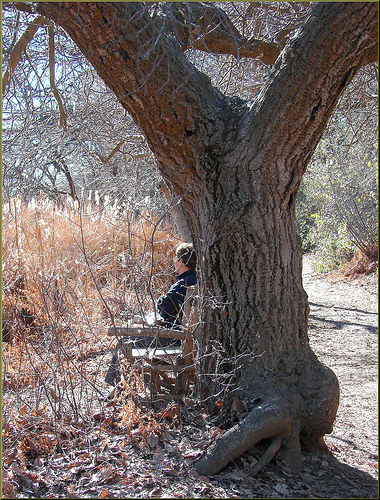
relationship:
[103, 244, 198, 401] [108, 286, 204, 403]
man on bench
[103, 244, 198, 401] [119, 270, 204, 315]
man wearing jacket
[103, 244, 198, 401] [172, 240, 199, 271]
man has hair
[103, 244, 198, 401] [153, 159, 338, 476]
man beside tree trunk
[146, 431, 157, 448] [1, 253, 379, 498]
leaf on ground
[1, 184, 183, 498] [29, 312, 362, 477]
grass on ground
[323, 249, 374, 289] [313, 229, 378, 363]
grass on ground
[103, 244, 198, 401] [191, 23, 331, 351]
man sitting next to tree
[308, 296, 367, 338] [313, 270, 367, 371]
shadow on ground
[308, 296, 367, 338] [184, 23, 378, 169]
shadow of limbs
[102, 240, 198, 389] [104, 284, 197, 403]
lady on bench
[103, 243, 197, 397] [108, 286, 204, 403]
lady on bench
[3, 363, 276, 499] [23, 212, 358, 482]
brown leaves on ground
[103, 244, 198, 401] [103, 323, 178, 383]
man wearing gray pants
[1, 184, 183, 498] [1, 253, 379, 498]
grass on ground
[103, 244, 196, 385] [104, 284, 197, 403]
man on bench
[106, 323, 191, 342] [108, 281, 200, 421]
arm of bench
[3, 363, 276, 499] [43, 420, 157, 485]
brown leaves on ground